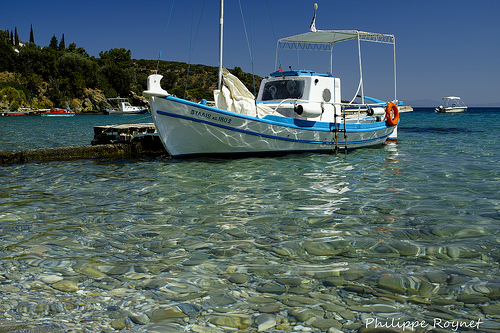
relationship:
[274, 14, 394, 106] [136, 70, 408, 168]
canopy attached to a boat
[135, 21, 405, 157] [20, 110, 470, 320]
boat on the lake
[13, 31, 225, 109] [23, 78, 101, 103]
hill with shrubs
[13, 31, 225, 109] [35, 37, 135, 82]
hill with trees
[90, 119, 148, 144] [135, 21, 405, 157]
deck next to boat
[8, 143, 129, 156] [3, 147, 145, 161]
metal covered in moss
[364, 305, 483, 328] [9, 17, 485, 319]
person who took the picture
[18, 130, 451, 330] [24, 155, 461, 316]
water with rocks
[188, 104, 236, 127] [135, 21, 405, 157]
name of the boat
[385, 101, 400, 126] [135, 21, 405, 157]
life preserver on the boat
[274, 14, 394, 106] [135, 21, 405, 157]
canopy on the boat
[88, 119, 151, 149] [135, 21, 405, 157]
dock near the boat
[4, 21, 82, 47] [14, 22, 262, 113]
trees in the background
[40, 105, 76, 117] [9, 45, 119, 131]
boat in the background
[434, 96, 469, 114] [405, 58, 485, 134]
boat in the background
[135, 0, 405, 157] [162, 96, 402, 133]
boat with trim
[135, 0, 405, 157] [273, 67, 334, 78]
boat with trim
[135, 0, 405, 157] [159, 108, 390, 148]
boat with trim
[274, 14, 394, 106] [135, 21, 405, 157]
canopy on rear of boat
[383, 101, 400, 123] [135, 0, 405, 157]
life preserver on side of boat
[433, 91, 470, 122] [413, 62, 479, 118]
boat sailing in distance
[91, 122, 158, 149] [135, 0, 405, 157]
dock next to boat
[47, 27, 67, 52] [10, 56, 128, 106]
trees on top of hill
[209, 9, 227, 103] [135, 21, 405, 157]
mast on boat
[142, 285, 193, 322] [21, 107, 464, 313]
rocks in the water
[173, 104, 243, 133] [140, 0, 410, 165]
words are on boat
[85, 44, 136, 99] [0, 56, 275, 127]
trees are on hill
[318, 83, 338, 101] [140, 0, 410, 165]
window on boat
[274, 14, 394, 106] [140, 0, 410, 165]
canopy on boat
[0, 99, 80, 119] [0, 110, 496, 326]
boat in water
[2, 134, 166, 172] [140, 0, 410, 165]
pier next to boat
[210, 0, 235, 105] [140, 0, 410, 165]
pole on boat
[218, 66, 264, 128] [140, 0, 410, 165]
tarp on boat